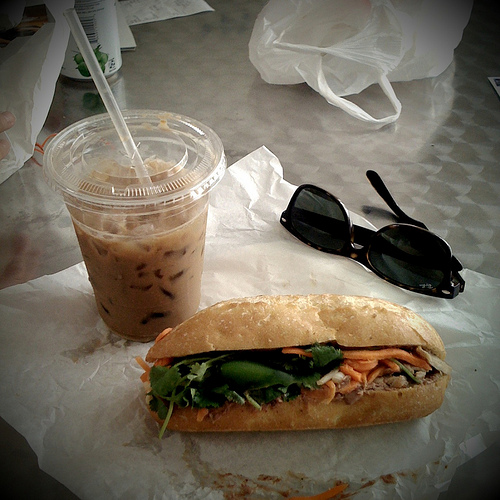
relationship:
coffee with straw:
[63, 145, 217, 346] [65, 37, 174, 210]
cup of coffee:
[45, 107, 229, 346] [63, 145, 217, 346]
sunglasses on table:
[280, 168, 467, 300] [8, 4, 498, 487]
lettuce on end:
[145, 345, 345, 438] [125, 282, 281, 424]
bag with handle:
[244, 3, 475, 131] [271, 7, 395, 65]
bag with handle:
[244, 3, 475, 131] [298, 54, 412, 128]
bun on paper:
[133, 286, 450, 435] [0, 146, 500, 499]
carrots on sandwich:
[146, 312, 471, 424] [141, 302, 453, 437]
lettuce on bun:
[145, 345, 345, 438] [133, 286, 450, 435]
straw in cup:
[59, 56, 146, 133] [106, 129, 283, 316]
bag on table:
[244, 3, 475, 131] [133, 20, 498, 225]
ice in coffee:
[127, 239, 201, 316] [72, 155, 208, 339]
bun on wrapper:
[133, 286, 450, 435] [10, 145, 497, 498]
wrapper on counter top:
[10, 145, 497, 498] [6, 0, 494, 498]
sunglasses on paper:
[280, 168, 467, 300] [0, 146, 500, 499]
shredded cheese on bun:
[340, 345, 432, 387] [133, 286, 450, 435]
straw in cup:
[61, 8, 159, 209] [25, 52, 232, 361]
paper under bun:
[4, 147, 491, 493] [133, 286, 450, 435]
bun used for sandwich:
[133, 286, 462, 447] [112, 276, 484, 450]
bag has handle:
[244, 3, 484, 147] [310, 55, 408, 131]